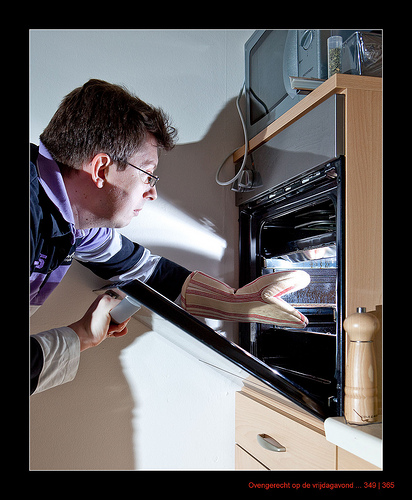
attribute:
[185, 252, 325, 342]
mitt — light yellow, red, oven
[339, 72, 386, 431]
panel — wooden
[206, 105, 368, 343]
microwave — silver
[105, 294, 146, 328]
handle — oven door's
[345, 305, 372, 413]
grinder — light brown, wooden, pepper grinder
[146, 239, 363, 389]
oven mitt — beige, red, striped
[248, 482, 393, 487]
text — orange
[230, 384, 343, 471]
door — pale wood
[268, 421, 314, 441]
woodgrain — blond , Pale 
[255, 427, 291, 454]
handle — silver, thin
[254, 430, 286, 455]
handle — silver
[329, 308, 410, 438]
shaker — pepper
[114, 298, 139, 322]
handle — grey 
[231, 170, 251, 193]
oven knobs — silver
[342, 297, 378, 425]
pepper dispenser — tall, wooden, thick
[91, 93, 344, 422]
oven — round , open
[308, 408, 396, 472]
counter — white, rounded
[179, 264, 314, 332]
oven mitt — striped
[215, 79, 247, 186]
cord — gray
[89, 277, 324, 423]
door — open, oven door